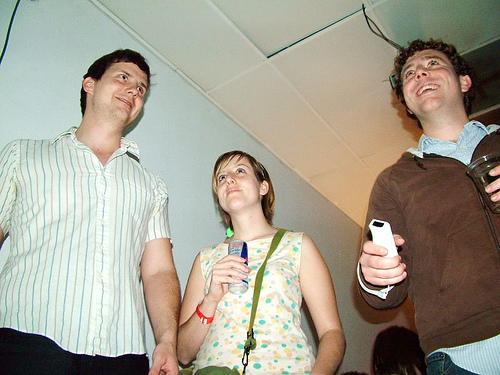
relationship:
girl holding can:
[202, 138, 267, 227] [218, 235, 249, 290]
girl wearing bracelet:
[202, 138, 267, 227] [190, 293, 218, 325]